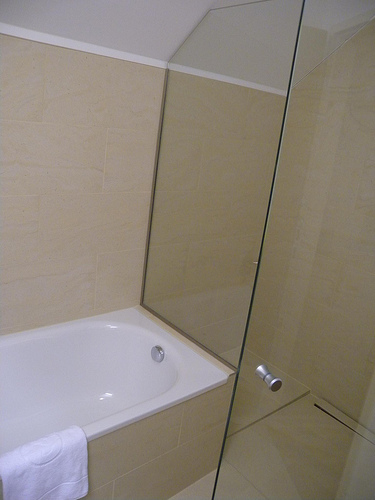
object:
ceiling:
[0, 0, 217, 64]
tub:
[0, 305, 228, 473]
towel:
[0, 423, 89, 499]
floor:
[164, 463, 217, 499]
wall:
[0, 34, 168, 334]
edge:
[191, 360, 241, 396]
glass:
[211, 0, 374, 499]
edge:
[76, 418, 101, 453]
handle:
[254, 358, 283, 394]